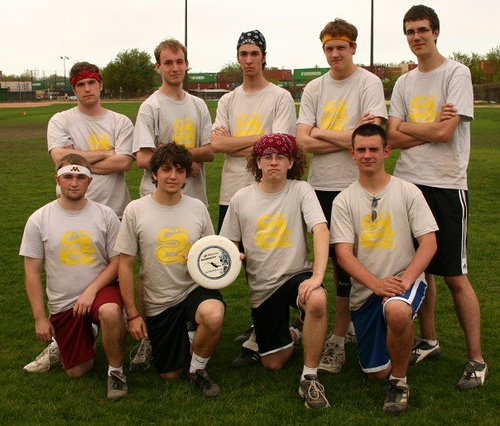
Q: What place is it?
A: It is a field.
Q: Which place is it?
A: It is a field.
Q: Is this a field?
A: Yes, it is a field.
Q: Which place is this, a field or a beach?
A: It is a field.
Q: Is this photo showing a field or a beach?
A: It is showing a field.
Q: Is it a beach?
A: No, it is a field.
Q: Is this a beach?
A: No, it is a field.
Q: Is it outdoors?
A: Yes, it is outdoors.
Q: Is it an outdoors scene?
A: Yes, it is outdoors.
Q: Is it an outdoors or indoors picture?
A: It is outdoors.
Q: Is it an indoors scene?
A: No, it is outdoors.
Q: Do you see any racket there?
A: No, there are no rackets.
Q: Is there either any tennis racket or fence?
A: No, there are no rackets or fences.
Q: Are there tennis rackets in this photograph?
A: No, there are no tennis rackets.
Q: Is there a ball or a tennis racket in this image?
A: No, there are no rackets or balls.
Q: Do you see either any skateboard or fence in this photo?
A: No, there are no skateboards or fences.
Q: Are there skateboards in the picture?
A: No, there are no skateboards.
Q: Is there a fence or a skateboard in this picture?
A: No, there are no skateboards or fences.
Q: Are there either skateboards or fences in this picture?
A: No, there are no fences or skateboards.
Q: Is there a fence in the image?
A: No, there are no fences.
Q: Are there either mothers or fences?
A: No, there are no fences or mothers.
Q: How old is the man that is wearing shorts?
A: The man is young.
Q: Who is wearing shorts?
A: The man is wearing shorts.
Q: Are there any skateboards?
A: No, there are no skateboards.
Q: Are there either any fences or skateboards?
A: No, there are no skateboards or fences.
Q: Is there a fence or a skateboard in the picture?
A: No, there are no skateboards or fences.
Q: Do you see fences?
A: No, there are no fences.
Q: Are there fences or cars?
A: No, there are no fences or cars.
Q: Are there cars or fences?
A: No, there are no fences or cars.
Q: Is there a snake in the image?
A: Yes, there is a snake.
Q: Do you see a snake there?
A: Yes, there is a snake.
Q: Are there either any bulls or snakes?
A: Yes, there is a snake.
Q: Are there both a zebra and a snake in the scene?
A: No, there is a snake but no zebras.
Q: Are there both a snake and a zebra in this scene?
A: No, there is a snake but no zebras.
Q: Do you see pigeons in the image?
A: No, there are no pigeons.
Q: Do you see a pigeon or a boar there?
A: No, there are no pigeons or boars.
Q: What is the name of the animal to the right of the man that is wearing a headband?
A: The animal is a snake.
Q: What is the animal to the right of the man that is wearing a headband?
A: The animal is a snake.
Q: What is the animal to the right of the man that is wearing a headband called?
A: The animal is a snake.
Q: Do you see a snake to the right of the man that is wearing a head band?
A: Yes, there is a snake to the right of the man.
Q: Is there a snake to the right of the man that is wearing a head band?
A: Yes, there is a snake to the right of the man.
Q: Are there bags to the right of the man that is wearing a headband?
A: No, there is a snake to the right of the man.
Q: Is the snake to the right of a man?
A: Yes, the snake is to the right of a man.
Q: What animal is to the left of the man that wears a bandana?
A: The animal is a snake.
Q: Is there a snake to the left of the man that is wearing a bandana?
A: Yes, there is a snake to the left of the man.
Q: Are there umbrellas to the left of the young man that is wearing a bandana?
A: No, there is a snake to the left of the man.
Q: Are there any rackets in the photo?
A: No, there are no rackets.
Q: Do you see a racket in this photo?
A: No, there are no rackets.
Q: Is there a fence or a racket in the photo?
A: No, there are no rackets or fences.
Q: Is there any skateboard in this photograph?
A: No, there are no skateboards.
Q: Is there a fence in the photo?
A: No, there are no fences.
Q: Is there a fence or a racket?
A: No, there are no fences or rackets.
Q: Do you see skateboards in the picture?
A: No, there are no skateboards.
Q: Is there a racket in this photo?
A: No, there are no rackets.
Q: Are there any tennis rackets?
A: No, there are no tennis rackets.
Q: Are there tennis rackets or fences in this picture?
A: No, there are no tennis rackets or fences.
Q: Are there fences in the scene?
A: No, there are no fences.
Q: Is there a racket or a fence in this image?
A: No, there are no fences or rackets.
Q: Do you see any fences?
A: No, there are no fences.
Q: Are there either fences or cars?
A: No, there are no fences or cars.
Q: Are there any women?
A: No, there are no women.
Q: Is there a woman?
A: No, there are no women.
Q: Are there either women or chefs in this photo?
A: No, there are no women or chefs.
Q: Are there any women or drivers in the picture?
A: No, there are no women or drivers.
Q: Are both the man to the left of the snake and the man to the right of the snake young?
A: Yes, both the man and the man are young.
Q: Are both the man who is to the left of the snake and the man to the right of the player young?
A: Yes, both the man and the man are young.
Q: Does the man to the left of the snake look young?
A: Yes, the man is young.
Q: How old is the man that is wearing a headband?
A: The man is young.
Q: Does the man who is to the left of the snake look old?
A: No, the man is young.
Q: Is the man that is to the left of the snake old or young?
A: The man is young.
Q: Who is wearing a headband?
A: The man is wearing a headband.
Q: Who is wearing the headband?
A: The man is wearing a headband.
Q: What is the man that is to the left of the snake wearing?
A: The man is wearing a headband.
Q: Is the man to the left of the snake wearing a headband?
A: Yes, the man is wearing a headband.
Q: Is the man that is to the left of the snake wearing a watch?
A: No, the man is wearing a headband.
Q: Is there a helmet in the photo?
A: No, there are no helmets.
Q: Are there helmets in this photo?
A: No, there are no helmets.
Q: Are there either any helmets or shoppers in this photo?
A: No, there are no helmets or shoppers.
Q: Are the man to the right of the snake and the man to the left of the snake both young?
A: Yes, both the man and the man are young.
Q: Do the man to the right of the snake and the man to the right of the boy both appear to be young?
A: Yes, both the man and the man are young.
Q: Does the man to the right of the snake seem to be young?
A: Yes, the man is young.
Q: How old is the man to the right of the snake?
A: The man is young.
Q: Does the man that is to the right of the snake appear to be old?
A: No, the man is young.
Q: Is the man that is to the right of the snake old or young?
A: The man is young.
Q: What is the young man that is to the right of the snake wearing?
A: The man is wearing a bandana.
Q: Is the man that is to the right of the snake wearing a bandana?
A: Yes, the man is wearing a bandana.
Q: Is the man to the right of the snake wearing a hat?
A: No, the man is wearing a bandana.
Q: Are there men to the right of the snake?
A: Yes, there is a man to the right of the snake.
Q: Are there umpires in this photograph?
A: No, there are no umpires.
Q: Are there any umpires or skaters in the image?
A: No, there are no umpires or skaters.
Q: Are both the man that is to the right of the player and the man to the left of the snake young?
A: Yes, both the man and the man are young.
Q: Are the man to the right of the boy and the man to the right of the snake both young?
A: Yes, both the man and the man are young.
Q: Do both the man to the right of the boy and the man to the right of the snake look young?
A: Yes, both the man and the man are young.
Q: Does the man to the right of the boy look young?
A: Yes, the man is young.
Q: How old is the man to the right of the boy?
A: The man is young.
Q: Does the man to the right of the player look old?
A: No, the man is young.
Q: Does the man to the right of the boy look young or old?
A: The man is young.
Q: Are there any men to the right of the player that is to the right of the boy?
A: Yes, there is a man to the right of the player.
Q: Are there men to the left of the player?
A: No, the man is to the right of the player.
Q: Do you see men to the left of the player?
A: No, the man is to the right of the player.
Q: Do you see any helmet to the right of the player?
A: No, there is a man to the right of the player.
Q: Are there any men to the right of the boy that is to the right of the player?
A: Yes, there is a man to the right of the boy.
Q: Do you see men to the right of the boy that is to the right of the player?
A: Yes, there is a man to the right of the boy.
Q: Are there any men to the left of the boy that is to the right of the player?
A: No, the man is to the right of the boy.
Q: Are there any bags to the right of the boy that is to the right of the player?
A: No, there is a man to the right of the boy.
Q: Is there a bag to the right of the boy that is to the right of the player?
A: No, there is a man to the right of the boy.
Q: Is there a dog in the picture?
A: No, there are no dogs.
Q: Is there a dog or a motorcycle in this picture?
A: No, there are no dogs or motorcycles.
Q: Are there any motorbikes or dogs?
A: No, there are no dogs or motorbikes.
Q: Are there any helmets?
A: No, there are no helmets.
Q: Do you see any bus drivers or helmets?
A: No, there are no helmets or bus drivers.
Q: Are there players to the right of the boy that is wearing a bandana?
A: Yes, there is a player to the right of the boy.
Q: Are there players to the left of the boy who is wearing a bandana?
A: No, the player is to the right of the boy.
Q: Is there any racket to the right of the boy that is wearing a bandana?
A: No, there is a player to the right of the boy.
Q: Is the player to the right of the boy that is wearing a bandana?
A: Yes, the player is to the right of the boy.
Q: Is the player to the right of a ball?
A: No, the player is to the right of the boy.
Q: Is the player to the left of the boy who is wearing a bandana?
A: No, the player is to the right of the boy.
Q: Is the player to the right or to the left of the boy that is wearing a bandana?
A: The player is to the right of the boy.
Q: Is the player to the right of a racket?
A: No, the player is to the right of a boy.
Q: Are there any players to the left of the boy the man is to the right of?
A: Yes, there is a player to the left of the boy.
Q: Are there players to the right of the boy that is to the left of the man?
A: No, the player is to the left of the boy.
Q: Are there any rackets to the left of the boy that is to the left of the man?
A: No, there is a player to the left of the boy.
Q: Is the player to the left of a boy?
A: Yes, the player is to the left of a boy.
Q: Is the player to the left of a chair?
A: No, the player is to the left of a boy.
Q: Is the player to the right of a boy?
A: No, the player is to the left of a boy.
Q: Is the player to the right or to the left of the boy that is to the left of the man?
A: The player is to the left of the boy.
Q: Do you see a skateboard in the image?
A: No, there are no skateboards.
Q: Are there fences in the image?
A: No, there are no fences.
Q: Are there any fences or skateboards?
A: No, there are no fences or skateboards.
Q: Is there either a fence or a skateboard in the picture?
A: No, there are no fences or skateboards.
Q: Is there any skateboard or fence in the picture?
A: No, there are no fences or skateboards.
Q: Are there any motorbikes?
A: No, there are no motorbikes.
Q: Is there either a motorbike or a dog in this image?
A: No, there are no motorcycles or dogs.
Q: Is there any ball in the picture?
A: No, there are no balls.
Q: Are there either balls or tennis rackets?
A: No, there are no balls or tennis rackets.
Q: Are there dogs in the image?
A: No, there are no dogs.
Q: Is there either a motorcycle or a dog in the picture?
A: No, there are no dogs or motorcycles.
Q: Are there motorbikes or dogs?
A: No, there are no dogs or motorbikes.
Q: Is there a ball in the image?
A: No, there are no balls.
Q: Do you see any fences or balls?
A: No, there are no balls or fences.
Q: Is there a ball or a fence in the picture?
A: No, there are no balls or fences.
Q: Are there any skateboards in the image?
A: No, there are no skateboards.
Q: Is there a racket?
A: No, there are no rackets.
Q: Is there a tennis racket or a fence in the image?
A: No, there are no rackets or fences.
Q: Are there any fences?
A: No, there are no fences.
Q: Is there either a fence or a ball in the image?
A: No, there are no fences or balls.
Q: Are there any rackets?
A: No, there are no rackets.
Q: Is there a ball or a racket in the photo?
A: No, there are no rackets or balls.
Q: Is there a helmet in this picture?
A: No, there are no helmets.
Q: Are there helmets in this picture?
A: No, there are no helmets.